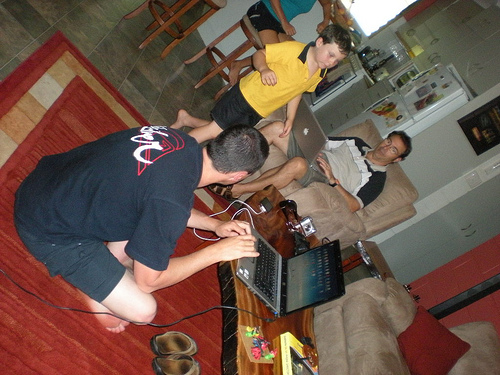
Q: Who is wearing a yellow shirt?
A: A young boy.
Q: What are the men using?
A: Laptop computers.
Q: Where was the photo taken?
A: In a living room.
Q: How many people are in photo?
A: Four.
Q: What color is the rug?
A: Orange.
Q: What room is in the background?
A: The kitchen.